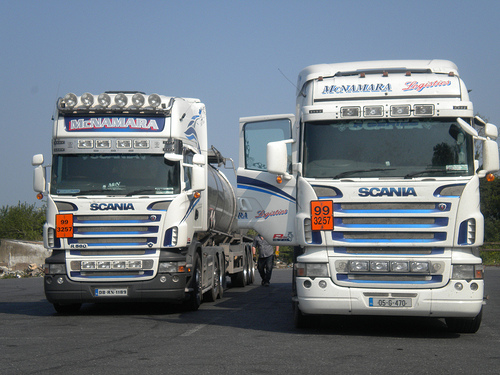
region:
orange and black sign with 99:
[300, 195, 342, 246]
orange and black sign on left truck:
[51, 200, 85, 246]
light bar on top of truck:
[51, 79, 181, 106]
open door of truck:
[231, 93, 313, 244]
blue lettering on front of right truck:
[360, 174, 433, 208]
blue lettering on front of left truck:
[88, 183, 150, 231]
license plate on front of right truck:
[359, 276, 417, 318]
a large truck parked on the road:
[32, 88, 257, 310]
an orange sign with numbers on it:
[309, 202, 334, 234]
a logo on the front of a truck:
[356, 183, 417, 200]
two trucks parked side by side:
[30, 56, 499, 334]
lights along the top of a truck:
[60, 91, 165, 107]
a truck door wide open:
[238, 112, 300, 254]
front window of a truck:
[298, 111, 478, 181]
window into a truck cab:
[49, 151, 186, 202]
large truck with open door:
[234, 56, 499, 326]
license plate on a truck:
[363, 295, 416, 311]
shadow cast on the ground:
[168, 310, 289, 334]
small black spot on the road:
[379, 341, 413, 359]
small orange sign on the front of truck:
[292, 194, 347, 237]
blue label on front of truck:
[354, 181, 429, 199]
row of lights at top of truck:
[48, 88, 173, 113]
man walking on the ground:
[241, 226, 290, 288]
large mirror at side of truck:
[32, 150, 52, 199]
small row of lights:
[448, 278, 488, 296]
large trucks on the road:
[26, 35, 492, 321]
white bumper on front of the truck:
[288, 269, 485, 330]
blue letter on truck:
[88, 200, 100, 212]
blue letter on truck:
[97, 202, 106, 209]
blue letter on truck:
[106, 201, 114, 211]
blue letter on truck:
[111, 200, 125, 210]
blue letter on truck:
[123, 202, 135, 214]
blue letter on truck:
[357, 185, 368, 198]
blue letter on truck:
[370, 185, 379, 197]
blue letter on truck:
[378, 186, 391, 198]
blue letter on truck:
[387, 185, 402, 197]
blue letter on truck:
[403, 183, 418, 198]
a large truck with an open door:
[236, 57, 498, 333]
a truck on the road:
[233, 56, 498, 332]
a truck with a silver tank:
[30, 91, 255, 311]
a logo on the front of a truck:
[91, 202, 136, 211]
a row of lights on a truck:
[60, 93, 165, 110]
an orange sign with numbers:
[311, 198, 333, 231]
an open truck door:
[233, 113, 295, 248]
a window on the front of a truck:
[49, 149, 184, 197]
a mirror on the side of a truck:
[28, 151, 51, 196]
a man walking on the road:
[251, 223, 283, 289]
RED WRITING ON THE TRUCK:
[405, 75, 460, 89]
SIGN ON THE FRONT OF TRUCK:
[311, 200, 329, 227]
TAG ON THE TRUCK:
[365, 295, 412, 306]